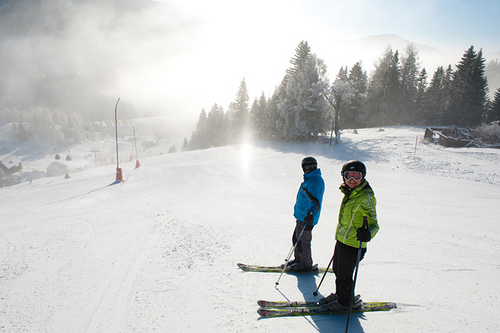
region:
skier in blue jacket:
[290, 146, 312, 263]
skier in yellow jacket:
[337, 165, 374, 301]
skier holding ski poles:
[323, 155, 393, 317]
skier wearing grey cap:
[268, 139, 325, 281]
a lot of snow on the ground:
[55, 135, 487, 312]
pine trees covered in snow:
[238, 42, 478, 143]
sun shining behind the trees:
[175, 32, 310, 169]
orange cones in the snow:
[106, 147, 170, 237]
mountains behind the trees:
[351, 15, 461, 132]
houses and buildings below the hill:
[0, 150, 102, 207]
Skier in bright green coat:
[342, 157, 373, 249]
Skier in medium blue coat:
[275, 143, 329, 270]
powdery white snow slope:
[65, 169, 463, 310]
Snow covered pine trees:
[236, 30, 480, 152]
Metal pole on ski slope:
[96, 83, 141, 175]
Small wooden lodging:
[1, 151, 21, 173]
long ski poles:
[289, 212, 299, 291]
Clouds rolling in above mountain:
[32, 25, 244, 117]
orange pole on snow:
[409, 137, 419, 158]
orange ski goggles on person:
[338, 165, 372, 192]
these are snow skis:
[240, 270, 411, 329]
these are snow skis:
[225, 240, 341, 282]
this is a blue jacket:
[292, 161, 332, 237]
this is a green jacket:
[331, 174, 388, 256]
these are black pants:
[293, 205, 320, 282]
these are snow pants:
[320, 237, 371, 330]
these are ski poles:
[304, 219, 374, 326]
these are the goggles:
[331, 162, 380, 192]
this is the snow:
[146, 214, 226, 302]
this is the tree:
[272, 35, 339, 146]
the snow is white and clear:
[58, 155, 169, 300]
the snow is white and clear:
[36, 82, 184, 323]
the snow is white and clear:
[90, 188, 158, 322]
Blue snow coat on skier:
[283, 152, 330, 233]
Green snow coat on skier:
[337, 163, 392, 249]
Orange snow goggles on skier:
[332, 168, 388, 182]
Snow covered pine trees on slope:
[263, 33, 494, 122]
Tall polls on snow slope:
[106, 93, 139, 175]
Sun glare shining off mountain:
[221, 97, 296, 167]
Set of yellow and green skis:
[251, 289, 415, 325]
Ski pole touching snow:
[319, 255, 330, 286]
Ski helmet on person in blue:
[293, 151, 324, 171]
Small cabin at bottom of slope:
[0, 152, 28, 173]